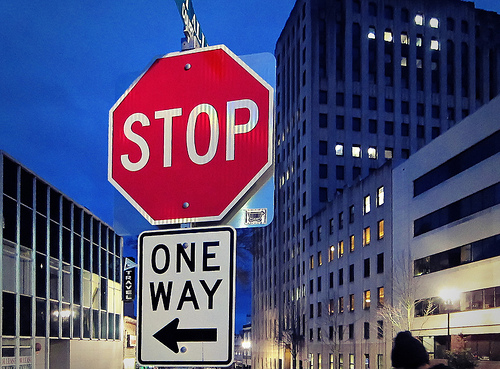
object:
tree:
[374, 257, 443, 338]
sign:
[135, 228, 236, 366]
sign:
[103, 48, 276, 226]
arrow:
[150, 316, 218, 353]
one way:
[148, 244, 223, 314]